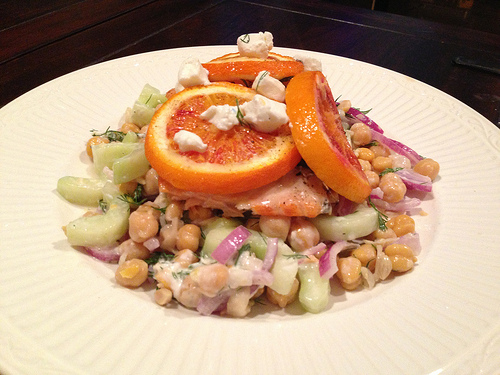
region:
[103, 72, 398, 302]
Food in the plate.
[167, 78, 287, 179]
Slices of orange on top of the food.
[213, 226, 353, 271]
Purple onions on the plate.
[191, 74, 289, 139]
Chucks of blue cheese on the plae.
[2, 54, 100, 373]
The plate is round.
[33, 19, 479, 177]
The plate is sitting on the table.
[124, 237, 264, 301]
A white creamy substance in the food.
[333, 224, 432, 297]
White peas in the food.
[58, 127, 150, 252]
Chopped cucumbers is mixed.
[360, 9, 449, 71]
The table is brown.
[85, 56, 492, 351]
foodon a plate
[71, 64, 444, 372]
food on a white plate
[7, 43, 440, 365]
a plate with a food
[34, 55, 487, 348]
a white plate with food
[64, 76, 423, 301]
a salad on a plate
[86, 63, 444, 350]
a salad on a white plate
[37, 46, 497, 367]
a plate with a sandwich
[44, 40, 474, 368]
a white plate with sandwich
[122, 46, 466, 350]
slices of cucumber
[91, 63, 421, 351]
slices of a red onion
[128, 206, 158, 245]
garbanzo bean covered in dressing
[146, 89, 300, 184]
slice of blood orange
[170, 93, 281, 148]
pieces of feta cheese on orange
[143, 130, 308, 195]
orange rind on blood orange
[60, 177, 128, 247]
light green cucumber slice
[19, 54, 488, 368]
white plate with salad on top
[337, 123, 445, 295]
garbanzo beans and onions on white plate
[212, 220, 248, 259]
small piece of chopped red onion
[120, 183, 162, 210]
sprigs of a green herb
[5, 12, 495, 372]
white plate with salad on dark wooden surface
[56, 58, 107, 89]
round edge of white plate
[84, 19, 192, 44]
lines on brown surface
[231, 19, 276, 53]
small piece of white cheese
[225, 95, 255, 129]
green herb on cheese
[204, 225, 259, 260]
sliver of purple onion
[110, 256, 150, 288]
small brown chick peas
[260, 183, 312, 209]
sauce covering food on plate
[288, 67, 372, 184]
slice of orange on plate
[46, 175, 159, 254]
cut piece of green celery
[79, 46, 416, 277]
food on white plate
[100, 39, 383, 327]
a plat full of food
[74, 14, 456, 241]
the plate is on table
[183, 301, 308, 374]
plate is white in color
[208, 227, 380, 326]
the onions are raw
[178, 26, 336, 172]
the food has white topimngs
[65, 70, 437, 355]
the plate is rounded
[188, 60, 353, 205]
the oranges are orane in color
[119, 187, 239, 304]
the food is brown in color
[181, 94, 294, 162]
the topings are apetising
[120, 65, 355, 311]
the food is delicious